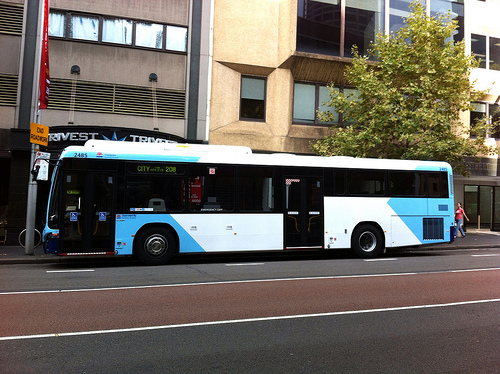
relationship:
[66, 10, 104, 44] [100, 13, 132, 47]
pane on window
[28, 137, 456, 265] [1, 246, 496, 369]
bus on street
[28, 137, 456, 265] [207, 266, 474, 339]
bus parked on street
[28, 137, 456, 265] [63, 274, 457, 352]
bus on street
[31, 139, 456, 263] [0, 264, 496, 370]
bus on street